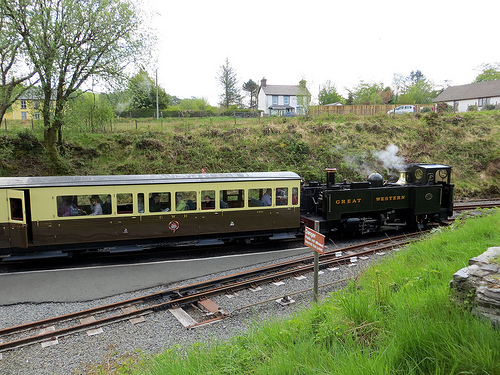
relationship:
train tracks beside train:
[1, 229, 430, 355] [1, 162, 457, 268]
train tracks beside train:
[452, 196, 499, 208] [1, 162, 457, 268]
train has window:
[1, 162, 457, 268] [56, 191, 113, 218]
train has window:
[1, 162, 457, 268] [116, 192, 134, 216]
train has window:
[1, 162, 457, 268] [136, 193, 146, 215]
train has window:
[1, 162, 457, 268] [147, 191, 172, 215]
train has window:
[1, 162, 457, 268] [175, 190, 198, 212]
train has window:
[1, 162, 457, 268] [200, 190, 219, 212]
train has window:
[1, 162, 457, 268] [220, 188, 247, 208]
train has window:
[1, 162, 457, 268] [246, 186, 274, 209]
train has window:
[1, 162, 457, 268] [274, 187, 290, 208]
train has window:
[1, 162, 457, 268] [291, 184, 300, 206]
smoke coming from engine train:
[338, 139, 408, 181] [298, 161, 454, 242]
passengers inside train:
[56, 190, 298, 218] [1, 162, 457, 268]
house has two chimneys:
[256, 75, 311, 120] [257, 77, 309, 88]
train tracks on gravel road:
[1, 229, 430, 355] [2, 231, 440, 375]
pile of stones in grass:
[450, 244, 499, 331] [117, 209, 500, 374]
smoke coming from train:
[338, 139, 408, 181] [1, 162, 457, 268]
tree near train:
[0, 0, 156, 161] [1, 162, 457, 268]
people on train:
[56, 190, 298, 218] [1, 162, 457, 268]